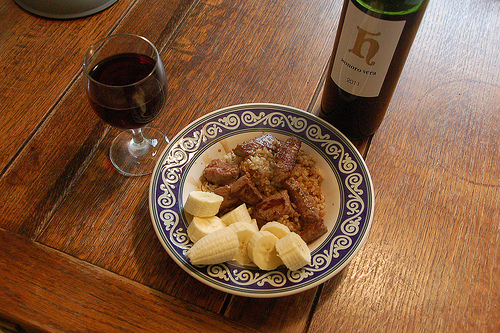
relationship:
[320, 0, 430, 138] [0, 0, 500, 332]
wine on table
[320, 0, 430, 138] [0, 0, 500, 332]
wine on top of table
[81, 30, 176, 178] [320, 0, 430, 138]
glass of wine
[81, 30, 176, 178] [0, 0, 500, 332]
glass on top of table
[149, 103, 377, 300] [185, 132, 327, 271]
bowl with food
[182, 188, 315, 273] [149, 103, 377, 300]
banana in bowl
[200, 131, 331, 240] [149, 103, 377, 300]
rice and meat in bowl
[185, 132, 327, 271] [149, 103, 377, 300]
food in bowl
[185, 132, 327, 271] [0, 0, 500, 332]
food on table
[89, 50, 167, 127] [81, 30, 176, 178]
wine in glass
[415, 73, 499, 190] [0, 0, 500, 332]
ring on table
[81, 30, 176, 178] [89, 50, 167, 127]
glass of wine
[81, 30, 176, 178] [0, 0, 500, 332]
glass on table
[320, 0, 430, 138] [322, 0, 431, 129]
wine in bottle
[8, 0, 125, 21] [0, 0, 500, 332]
pot on table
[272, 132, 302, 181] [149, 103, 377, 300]
meat on bowl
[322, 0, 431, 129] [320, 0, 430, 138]
bottle of wine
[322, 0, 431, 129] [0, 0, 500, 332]
bottle on table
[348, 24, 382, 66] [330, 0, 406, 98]
h on label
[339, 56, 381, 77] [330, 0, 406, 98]
words on label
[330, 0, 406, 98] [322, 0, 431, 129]
label on bottle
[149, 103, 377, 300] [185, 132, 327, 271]
bowl of food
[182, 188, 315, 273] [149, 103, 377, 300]
banana on bowl